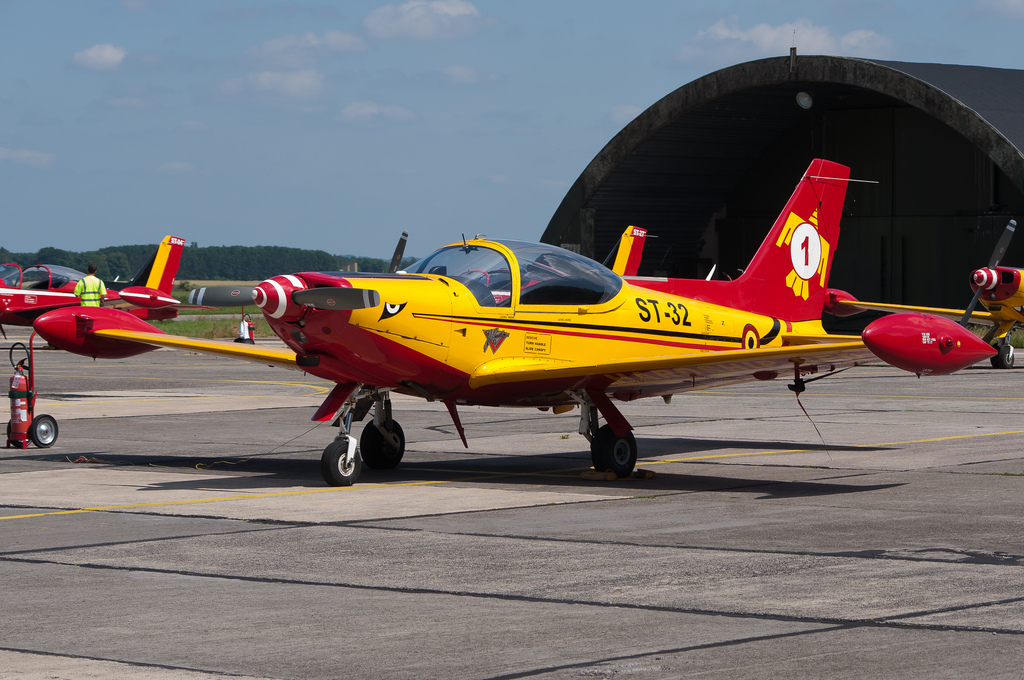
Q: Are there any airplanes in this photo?
A: Yes, there is an airplane.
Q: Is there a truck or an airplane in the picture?
A: Yes, there is an airplane.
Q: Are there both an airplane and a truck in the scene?
A: No, there is an airplane but no trucks.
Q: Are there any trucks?
A: No, there are no trucks.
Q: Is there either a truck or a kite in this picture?
A: No, there are no trucks or kites.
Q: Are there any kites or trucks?
A: No, there are no trucks or kites.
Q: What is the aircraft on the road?
A: The aircraft is an airplane.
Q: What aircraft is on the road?
A: The aircraft is an airplane.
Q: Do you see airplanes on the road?
A: Yes, there is an airplane on the road.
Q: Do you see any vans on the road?
A: No, there is an airplane on the road.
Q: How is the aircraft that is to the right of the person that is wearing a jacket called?
A: The aircraft is an airplane.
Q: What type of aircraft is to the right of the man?
A: The aircraft is an airplane.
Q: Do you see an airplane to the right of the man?
A: Yes, there is an airplane to the right of the man.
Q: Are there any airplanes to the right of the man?
A: Yes, there is an airplane to the right of the man.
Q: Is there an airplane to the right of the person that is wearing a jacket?
A: Yes, there is an airplane to the right of the man.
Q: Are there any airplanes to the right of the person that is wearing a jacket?
A: Yes, there is an airplane to the right of the man.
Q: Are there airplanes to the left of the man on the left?
A: No, the airplane is to the right of the man.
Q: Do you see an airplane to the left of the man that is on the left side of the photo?
A: No, the airplane is to the right of the man.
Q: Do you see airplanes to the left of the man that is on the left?
A: No, the airplane is to the right of the man.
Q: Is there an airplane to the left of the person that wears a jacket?
A: No, the airplane is to the right of the man.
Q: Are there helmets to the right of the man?
A: No, there is an airplane to the right of the man.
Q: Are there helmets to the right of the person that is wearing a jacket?
A: No, there is an airplane to the right of the man.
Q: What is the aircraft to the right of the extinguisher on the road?
A: The aircraft is an airplane.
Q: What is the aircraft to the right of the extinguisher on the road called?
A: The aircraft is an airplane.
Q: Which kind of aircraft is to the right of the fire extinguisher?
A: The aircraft is an airplane.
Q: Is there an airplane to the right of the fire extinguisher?
A: Yes, there is an airplane to the right of the fire extinguisher.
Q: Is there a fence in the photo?
A: No, there are no fences.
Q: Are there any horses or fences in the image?
A: No, there are no fences or horses.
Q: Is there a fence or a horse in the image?
A: No, there are no fences or horses.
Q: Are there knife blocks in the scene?
A: No, there are no knife blocks.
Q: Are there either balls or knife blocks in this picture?
A: No, there are no knife blocks or balls.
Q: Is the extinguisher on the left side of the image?
A: Yes, the extinguisher is on the left of the image.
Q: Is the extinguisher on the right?
A: No, the extinguisher is on the left of the image.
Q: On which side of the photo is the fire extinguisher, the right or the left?
A: The fire extinguisher is on the left of the image.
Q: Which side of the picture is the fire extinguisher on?
A: The fire extinguisher is on the left of the image.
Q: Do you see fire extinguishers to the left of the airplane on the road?
A: Yes, there is a fire extinguisher to the left of the plane.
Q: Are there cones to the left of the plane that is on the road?
A: No, there is a fire extinguisher to the left of the airplane.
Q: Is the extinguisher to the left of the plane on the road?
A: Yes, the extinguisher is to the left of the plane.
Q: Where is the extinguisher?
A: The extinguisher is on the road.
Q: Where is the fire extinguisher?
A: The extinguisher is on the road.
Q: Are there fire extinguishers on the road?
A: Yes, there is a fire extinguisher on the road.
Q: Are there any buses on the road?
A: No, there is a fire extinguisher on the road.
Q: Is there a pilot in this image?
A: No, there are no pilots.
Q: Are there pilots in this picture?
A: No, there are no pilots.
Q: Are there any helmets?
A: No, there are no helmets.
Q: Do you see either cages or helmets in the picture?
A: No, there are no helmets or cages.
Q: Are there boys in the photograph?
A: No, there are no boys.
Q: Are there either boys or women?
A: No, there are no boys or women.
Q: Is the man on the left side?
A: Yes, the man is on the left of the image.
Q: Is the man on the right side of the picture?
A: No, the man is on the left of the image.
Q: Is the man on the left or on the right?
A: The man is on the left of the image.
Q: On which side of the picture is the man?
A: The man is on the left of the image.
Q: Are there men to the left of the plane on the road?
A: Yes, there is a man to the left of the airplane.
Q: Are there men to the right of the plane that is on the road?
A: No, the man is to the left of the airplane.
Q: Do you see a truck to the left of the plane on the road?
A: No, there is a man to the left of the plane.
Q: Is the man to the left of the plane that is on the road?
A: Yes, the man is to the left of the plane.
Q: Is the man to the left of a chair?
A: No, the man is to the left of the plane.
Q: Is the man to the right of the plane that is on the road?
A: No, the man is to the left of the airplane.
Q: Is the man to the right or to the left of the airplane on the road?
A: The man is to the left of the plane.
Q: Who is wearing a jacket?
A: The man is wearing a jacket.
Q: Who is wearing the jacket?
A: The man is wearing a jacket.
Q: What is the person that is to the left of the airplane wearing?
A: The man is wearing a jacket.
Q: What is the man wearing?
A: The man is wearing a jacket.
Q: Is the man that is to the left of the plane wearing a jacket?
A: Yes, the man is wearing a jacket.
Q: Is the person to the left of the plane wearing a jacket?
A: Yes, the man is wearing a jacket.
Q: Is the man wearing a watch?
A: No, the man is wearing a jacket.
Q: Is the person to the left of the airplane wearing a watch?
A: No, the man is wearing a jacket.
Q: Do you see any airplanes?
A: Yes, there is an airplane.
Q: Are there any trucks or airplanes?
A: Yes, there is an airplane.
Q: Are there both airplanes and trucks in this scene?
A: No, there is an airplane but no trucks.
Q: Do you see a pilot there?
A: No, there are no pilots.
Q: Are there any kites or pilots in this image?
A: No, there are no pilots or kites.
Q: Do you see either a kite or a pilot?
A: No, there are no pilots or kites.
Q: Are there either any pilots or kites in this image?
A: No, there are no pilots or kites.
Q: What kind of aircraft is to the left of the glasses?
A: The aircraft is an airplane.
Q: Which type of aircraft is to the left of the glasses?
A: The aircraft is an airplane.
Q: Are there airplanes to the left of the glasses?
A: Yes, there is an airplane to the left of the glasses.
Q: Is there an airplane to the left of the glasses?
A: Yes, there is an airplane to the left of the glasses.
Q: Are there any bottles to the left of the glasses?
A: No, there is an airplane to the left of the glasses.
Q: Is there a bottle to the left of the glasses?
A: No, there is an airplane to the left of the glasses.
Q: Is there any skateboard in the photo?
A: No, there are no skateboards.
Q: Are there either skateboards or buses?
A: No, there are no skateboards or buses.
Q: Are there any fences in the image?
A: No, there are no fences.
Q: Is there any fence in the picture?
A: No, there are no fences.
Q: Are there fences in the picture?
A: No, there are no fences.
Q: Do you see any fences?
A: No, there are no fences.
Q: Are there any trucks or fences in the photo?
A: No, there are no fences or trucks.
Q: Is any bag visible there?
A: No, there are no bags.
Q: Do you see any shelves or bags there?
A: No, there are no bags or shelves.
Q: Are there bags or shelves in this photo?
A: No, there are no bags or shelves.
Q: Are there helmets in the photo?
A: No, there are no helmets.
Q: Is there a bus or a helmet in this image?
A: No, there are no helmets or buses.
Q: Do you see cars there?
A: No, there are no cars.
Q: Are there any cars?
A: No, there are no cars.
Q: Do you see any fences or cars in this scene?
A: No, there are no cars or fences.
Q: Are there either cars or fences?
A: No, there are no cars or fences.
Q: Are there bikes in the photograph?
A: No, there are no bikes.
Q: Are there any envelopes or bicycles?
A: No, there are no bicycles or envelopes.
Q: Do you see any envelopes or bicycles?
A: No, there are no bicycles or envelopes.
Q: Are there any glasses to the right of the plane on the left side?
A: Yes, there are glasses to the right of the airplane.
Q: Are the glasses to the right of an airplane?
A: Yes, the glasses are to the right of an airplane.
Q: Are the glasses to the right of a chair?
A: No, the glasses are to the right of an airplane.